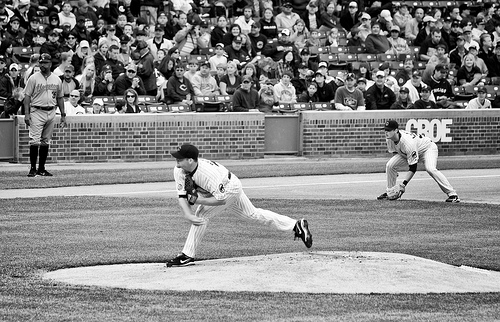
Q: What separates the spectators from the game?
A: A brick wall.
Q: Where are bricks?
A: On the wall.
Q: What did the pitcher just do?
A: Throw the ball.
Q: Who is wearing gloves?
A: Two players.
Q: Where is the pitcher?
A: On pitcher's mound.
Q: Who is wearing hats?
A: Two players.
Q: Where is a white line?
A: On the dirt.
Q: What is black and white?
A: Pitcher's sneakers.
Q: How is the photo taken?
A: In black and white.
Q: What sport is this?
A: Baseball.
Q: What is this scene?
A: A baseball game.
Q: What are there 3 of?
A: Players.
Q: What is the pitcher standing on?
A: The diamond.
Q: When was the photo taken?
A: Daytime.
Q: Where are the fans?
A: Stands.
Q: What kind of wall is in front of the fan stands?
A: Brick.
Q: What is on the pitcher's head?
A: Cap.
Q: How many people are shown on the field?
A: Three.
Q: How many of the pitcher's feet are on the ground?
A: One.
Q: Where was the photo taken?
A: Baseball field.